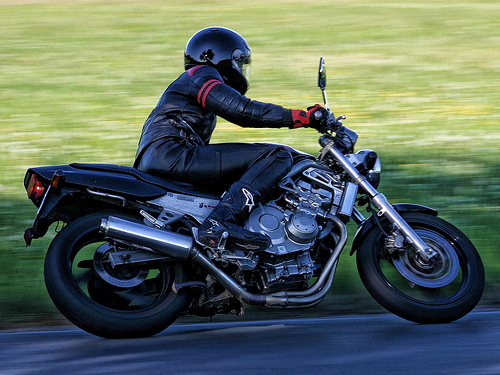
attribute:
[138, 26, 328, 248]
person — man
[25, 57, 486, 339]
motorcycle — silver, black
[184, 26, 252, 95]
helmet — motorcycle helmet, black, shiny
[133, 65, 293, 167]
jacket — leather, red, black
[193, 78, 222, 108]
stripes — red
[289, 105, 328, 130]
glove — red, leather, black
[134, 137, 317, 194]
pants — leather, black, shiny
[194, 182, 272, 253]
boot — leather, black, motorcycle boot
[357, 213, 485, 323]
front wheel — black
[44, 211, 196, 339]
rear wheel — black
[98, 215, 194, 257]
muffler — silver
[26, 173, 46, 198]
tail light — red, illuminated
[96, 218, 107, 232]
tail pipe — silver, shiny, metal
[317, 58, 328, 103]
rearview mirror — silver, shiny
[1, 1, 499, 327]
field — grassy, blurry, green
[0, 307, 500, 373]
road — asphalt, blurry, paved, black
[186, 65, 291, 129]
sleeve — leather, ribbed